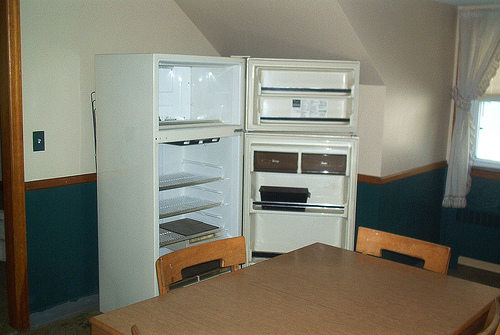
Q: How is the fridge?
A: Open.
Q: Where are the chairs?
A: Under table.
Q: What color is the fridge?
A: White.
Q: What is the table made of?
A: Wood.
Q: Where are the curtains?
A: On window.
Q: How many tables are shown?
A: One.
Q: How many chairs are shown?
A: Two.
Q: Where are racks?
A: In fridge.